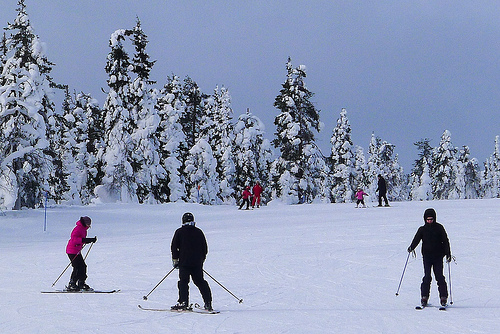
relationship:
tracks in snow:
[133, 310, 206, 332] [274, 270, 335, 311]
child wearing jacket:
[353, 182, 366, 209] [351, 187, 368, 199]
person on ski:
[405, 206, 456, 304] [437, 294, 459, 311]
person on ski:
[405, 206, 456, 304] [411, 294, 435, 315]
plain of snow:
[1, 197, 498, 332] [0, 199, 498, 332]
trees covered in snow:
[0, 0, 499, 203] [422, 173, 429, 197]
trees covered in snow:
[0, 0, 499, 203] [287, 122, 301, 139]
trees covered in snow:
[0, 0, 499, 203] [165, 158, 178, 172]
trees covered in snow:
[0, 0, 499, 203] [106, 151, 120, 170]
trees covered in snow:
[0, 0, 499, 203] [25, 90, 40, 112]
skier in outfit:
[238, 185, 250, 207] [250, 183, 258, 204]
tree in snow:
[328, 105, 355, 203] [3, 172, 495, 331]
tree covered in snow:
[266, 47, 321, 178] [0, 199, 498, 332]